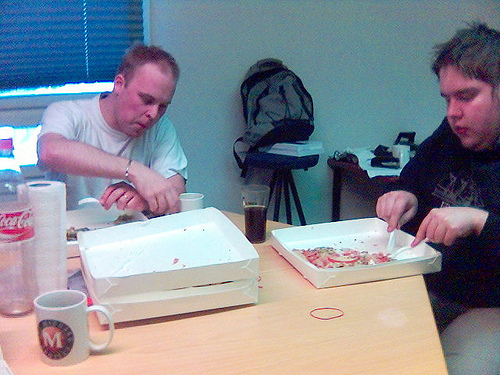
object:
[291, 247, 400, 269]
pizza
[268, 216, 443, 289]
box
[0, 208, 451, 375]
table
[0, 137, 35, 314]
bottle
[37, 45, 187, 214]
man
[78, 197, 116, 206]
fork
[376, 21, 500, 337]
man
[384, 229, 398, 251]
knife